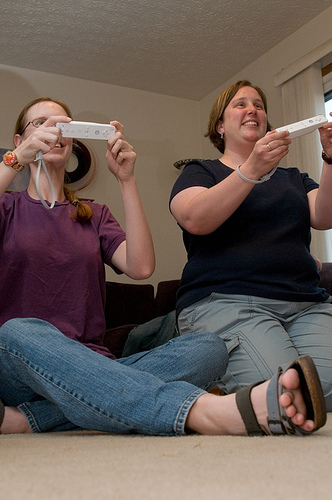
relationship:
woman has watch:
[3, 97, 330, 432] [5, 141, 27, 184]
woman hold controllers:
[167, 79, 331, 420] [46, 108, 325, 166]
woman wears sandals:
[3, 97, 330, 432] [186, 335, 309, 453]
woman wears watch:
[3, 97, 330, 432] [5, 141, 27, 184]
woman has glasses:
[3, 97, 330, 432] [30, 118, 82, 139]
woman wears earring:
[187, 94, 326, 404] [216, 132, 228, 142]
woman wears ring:
[187, 94, 326, 404] [265, 138, 289, 146]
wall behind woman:
[114, 91, 170, 244] [167, 79, 331, 420]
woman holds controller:
[3, 97, 330, 432] [51, 116, 114, 150]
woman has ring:
[187, 94, 326, 404] [265, 138, 289, 146]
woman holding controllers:
[167, 79, 331, 420] [46, 108, 325, 166]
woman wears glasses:
[3, 97, 330, 432] [30, 118, 82, 139]